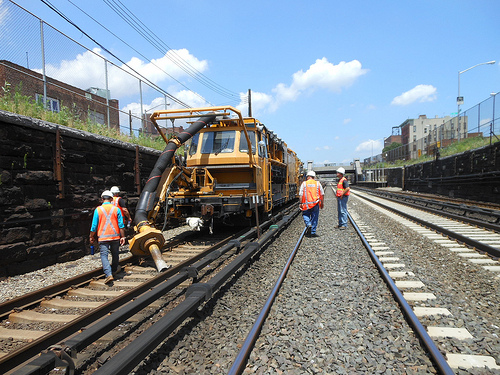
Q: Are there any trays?
A: No, there are no trays.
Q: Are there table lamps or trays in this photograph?
A: No, there are no trays or table lamps.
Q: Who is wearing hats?
A: The workers are wearing hats.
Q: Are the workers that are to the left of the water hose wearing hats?
A: Yes, the workers are wearing hats.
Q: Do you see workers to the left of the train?
A: Yes, there are workers to the left of the train.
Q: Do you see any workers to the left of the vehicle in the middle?
A: Yes, there are workers to the left of the train.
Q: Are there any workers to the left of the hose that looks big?
A: Yes, there are workers to the left of the water hose.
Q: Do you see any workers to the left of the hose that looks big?
A: Yes, there are workers to the left of the water hose.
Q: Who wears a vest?
A: The workers wear a vest.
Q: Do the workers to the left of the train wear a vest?
A: Yes, the workers wear a vest.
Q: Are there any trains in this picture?
A: Yes, there is a train.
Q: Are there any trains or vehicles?
A: Yes, there is a train.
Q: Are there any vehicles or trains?
A: Yes, there is a train.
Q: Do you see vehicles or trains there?
A: Yes, there is a train.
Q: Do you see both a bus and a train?
A: No, there is a train but no buses.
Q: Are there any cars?
A: No, there are no cars.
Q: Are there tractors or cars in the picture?
A: No, there are no cars or tractors.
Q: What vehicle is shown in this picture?
A: The vehicle is a train.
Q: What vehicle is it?
A: The vehicle is a train.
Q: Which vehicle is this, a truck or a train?
A: This is a train.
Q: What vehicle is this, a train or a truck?
A: This is a train.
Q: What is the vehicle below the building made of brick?
A: The vehicle is a train.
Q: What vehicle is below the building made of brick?
A: The vehicle is a train.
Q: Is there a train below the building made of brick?
A: Yes, there is a train below the building.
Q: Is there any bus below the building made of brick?
A: No, there is a train below the building.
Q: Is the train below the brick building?
A: Yes, the train is below the building.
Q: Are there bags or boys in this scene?
A: No, there are no bags or boys.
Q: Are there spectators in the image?
A: No, there are no spectators.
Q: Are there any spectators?
A: No, there are no spectators.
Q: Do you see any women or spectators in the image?
A: No, there are no spectators or women.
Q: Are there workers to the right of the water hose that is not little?
A: Yes, there are workers to the right of the water hose.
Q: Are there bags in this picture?
A: No, there are no bags.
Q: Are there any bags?
A: No, there are no bags.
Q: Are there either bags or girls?
A: No, there are no bags or girls.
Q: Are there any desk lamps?
A: No, there are no desk lamps.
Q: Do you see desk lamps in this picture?
A: No, there are no desk lamps.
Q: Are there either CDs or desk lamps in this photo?
A: No, there are no desk lamps or cds.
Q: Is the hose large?
A: Yes, the hose is large.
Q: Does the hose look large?
A: Yes, the hose is large.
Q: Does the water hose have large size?
A: Yes, the water hose is large.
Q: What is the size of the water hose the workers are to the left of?
A: The water hose is large.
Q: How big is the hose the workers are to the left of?
A: The water hose is large.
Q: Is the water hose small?
A: No, the water hose is large.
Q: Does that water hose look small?
A: No, the water hose is large.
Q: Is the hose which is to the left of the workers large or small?
A: The water hose is large.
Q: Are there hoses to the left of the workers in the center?
A: Yes, there is a hose to the left of the workers.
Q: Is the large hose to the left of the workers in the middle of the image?
A: Yes, the hose is to the left of the workers.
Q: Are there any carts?
A: No, there are no carts.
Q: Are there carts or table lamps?
A: No, there are no carts or table lamps.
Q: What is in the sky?
A: The clouds are in the sky.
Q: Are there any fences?
A: Yes, there is a fence.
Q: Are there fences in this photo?
A: Yes, there is a fence.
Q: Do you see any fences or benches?
A: Yes, there is a fence.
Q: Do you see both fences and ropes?
A: No, there is a fence but no ropes.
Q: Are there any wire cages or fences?
A: Yes, there is a wire fence.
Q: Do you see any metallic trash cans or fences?
A: Yes, there is a metal fence.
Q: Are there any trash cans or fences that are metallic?
A: Yes, the fence is metallic.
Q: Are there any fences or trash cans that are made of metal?
A: Yes, the fence is made of metal.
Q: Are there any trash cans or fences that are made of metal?
A: Yes, the fence is made of metal.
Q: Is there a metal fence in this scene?
A: Yes, there is a metal fence.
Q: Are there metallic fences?
A: Yes, there is a metal fence.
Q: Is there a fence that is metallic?
A: Yes, there is a fence that is metallic.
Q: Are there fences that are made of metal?
A: Yes, there is a fence that is made of metal.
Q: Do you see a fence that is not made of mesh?
A: Yes, there is a fence that is made of metal.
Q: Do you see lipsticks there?
A: No, there are no lipsticks.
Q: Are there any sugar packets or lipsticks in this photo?
A: No, there are no lipsticks or sugar packets.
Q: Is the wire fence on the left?
A: Yes, the fence is on the left of the image.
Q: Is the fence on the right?
A: No, the fence is on the left of the image.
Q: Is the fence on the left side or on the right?
A: The fence is on the left of the image.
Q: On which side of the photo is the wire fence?
A: The fence is on the left of the image.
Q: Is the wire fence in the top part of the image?
A: Yes, the fence is in the top of the image.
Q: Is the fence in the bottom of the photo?
A: No, the fence is in the top of the image.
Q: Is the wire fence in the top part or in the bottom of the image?
A: The fence is in the top of the image.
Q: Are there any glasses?
A: No, there are no glasses.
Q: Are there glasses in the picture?
A: No, there are no glasses.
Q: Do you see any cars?
A: No, there are no cars.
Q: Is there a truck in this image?
A: No, there are no trucks.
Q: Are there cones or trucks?
A: No, there are no trucks or cones.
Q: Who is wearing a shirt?
A: The workers are wearing a shirt.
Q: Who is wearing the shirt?
A: The workers are wearing a shirt.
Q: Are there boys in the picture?
A: No, there are no boys.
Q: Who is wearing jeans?
A: The workers are wearing jeans.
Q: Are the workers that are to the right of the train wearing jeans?
A: Yes, the workers are wearing jeans.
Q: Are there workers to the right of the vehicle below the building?
A: Yes, there are workers to the right of the train.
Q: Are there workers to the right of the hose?
A: Yes, there are workers to the right of the hose.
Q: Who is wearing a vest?
A: The workers are wearing a vest.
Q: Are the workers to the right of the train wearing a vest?
A: Yes, the workers are wearing a vest.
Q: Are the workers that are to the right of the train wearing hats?
A: Yes, the workers are wearing hats.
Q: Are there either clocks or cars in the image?
A: No, there are no cars or clocks.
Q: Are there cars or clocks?
A: No, there are no cars or clocks.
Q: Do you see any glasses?
A: No, there are no glasses.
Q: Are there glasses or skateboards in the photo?
A: No, there are no glasses or skateboards.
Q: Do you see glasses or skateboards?
A: No, there are no glasses or skateboards.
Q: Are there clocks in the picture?
A: No, there are no clocks.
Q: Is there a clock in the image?
A: No, there are no clocks.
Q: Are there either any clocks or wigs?
A: No, there are no clocks or wigs.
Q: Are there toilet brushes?
A: No, there are no toilet brushes.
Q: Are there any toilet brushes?
A: No, there are no toilet brushes.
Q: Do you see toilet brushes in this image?
A: No, there are no toilet brushes.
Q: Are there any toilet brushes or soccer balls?
A: No, there are no toilet brushes or soccer balls.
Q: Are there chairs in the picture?
A: No, there are no chairs.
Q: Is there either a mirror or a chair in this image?
A: No, there are no chairs or mirrors.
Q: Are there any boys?
A: No, there are no boys.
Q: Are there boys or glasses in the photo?
A: No, there are no boys or glasses.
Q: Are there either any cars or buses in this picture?
A: No, there are no cars or buses.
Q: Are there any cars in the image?
A: No, there are no cars.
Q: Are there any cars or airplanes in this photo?
A: No, there are no cars or airplanes.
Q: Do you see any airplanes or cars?
A: No, there are no cars or airplanes.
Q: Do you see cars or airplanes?
A: No, there are no cars or airplanes.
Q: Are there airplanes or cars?
A: No, there are no cars or airplanes.